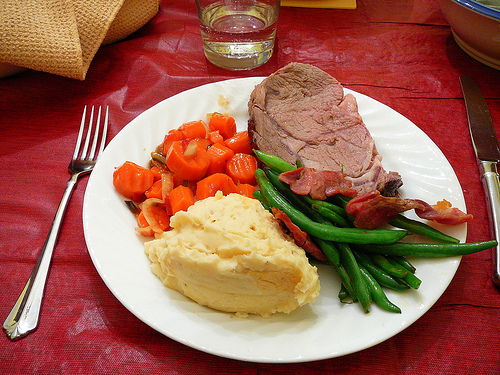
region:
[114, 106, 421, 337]
plate full of food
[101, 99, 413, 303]
food on white plate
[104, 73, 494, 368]
plate on red tablecloth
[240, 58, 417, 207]
cooked meat on plate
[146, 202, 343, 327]
mashed potatoes on plate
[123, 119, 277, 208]
cooked carrots on palte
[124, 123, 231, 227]
onion bits with carrots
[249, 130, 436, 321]
green beans on palte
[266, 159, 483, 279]
cooked bacon on green beans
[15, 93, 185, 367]
fork next to plate on red tablecloth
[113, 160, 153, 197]
a piece of cooked orange carrot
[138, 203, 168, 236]
a piece of cooked orange carrot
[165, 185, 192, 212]
a piece of cooked orange carrot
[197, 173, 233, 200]
a piece of cooked orange carrot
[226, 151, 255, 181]
a piece of cooked orange carrot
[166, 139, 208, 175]
a piece of cooked orange carrot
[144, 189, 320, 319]
a pile of mashed potatos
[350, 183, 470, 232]
a piece of bacon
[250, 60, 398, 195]
a piece of cooked steak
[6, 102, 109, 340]
a silver fork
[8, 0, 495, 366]
Place setting with a meal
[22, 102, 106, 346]
Fork near meal on left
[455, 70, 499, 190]
Butter knife near meal on right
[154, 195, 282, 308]
mashed potatoes line edge of plate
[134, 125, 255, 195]
cooked carrots with pieces of onion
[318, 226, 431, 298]
green beans to the right of potatoes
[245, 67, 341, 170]
piece of meat to the right of carrots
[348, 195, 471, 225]
bacon piece on top of green beans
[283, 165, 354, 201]
bacon piece ontop of green beans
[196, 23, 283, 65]
A glass of water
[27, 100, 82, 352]
a fork on the table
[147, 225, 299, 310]
amash potatoes on a plate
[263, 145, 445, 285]
asparagus with bacon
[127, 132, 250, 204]
carrots on a white plate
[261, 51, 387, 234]
a nice cut of meat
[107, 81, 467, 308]
a nice looking dinner plate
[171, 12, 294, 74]
a drink with dinner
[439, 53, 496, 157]
a butter knife to cut with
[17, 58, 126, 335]
a red table cloth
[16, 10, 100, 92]
a yellow linen cloth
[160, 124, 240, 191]
cooked orange carrots with onion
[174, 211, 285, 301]
golden mashed potatoes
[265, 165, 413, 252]
green beans with bacon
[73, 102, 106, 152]
silver fork tines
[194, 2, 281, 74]
glassclear drinking glass of water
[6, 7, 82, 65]
a patterned cloth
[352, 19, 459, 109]
red tablecloth is wrinkled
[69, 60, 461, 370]
white plate full of food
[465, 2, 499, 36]
bowl is blue and white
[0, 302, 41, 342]
decorative silver fork handle